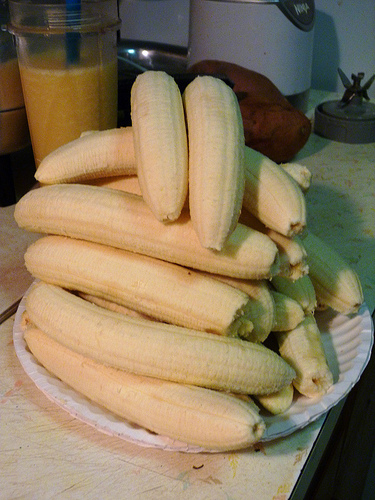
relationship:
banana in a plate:
[10, 184, 271, 267] [11, 306, 370, 439]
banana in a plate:
[103, 103, 307, 292] [12, 262, 373, 451]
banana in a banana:
[183, 72, 249, 254] [126, 65, 187, 226]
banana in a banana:
[183, 72, 249, 254] [30, 121, 309, 241]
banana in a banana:
[183, 72, 249, 254] [11, 180, 282, 282]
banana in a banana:
[183, 72, 249, 254] [18, 282, 300, 396]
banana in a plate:
[183, 72, 249, 254] [12, 262, 373, 451]